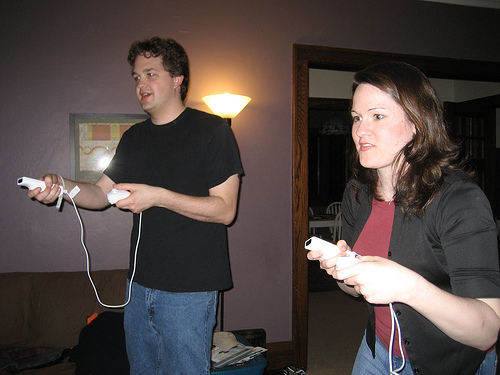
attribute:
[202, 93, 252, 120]
light — on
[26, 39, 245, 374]
man — playing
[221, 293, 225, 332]
pole — black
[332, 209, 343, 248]
chair — wooden, white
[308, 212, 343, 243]
table — white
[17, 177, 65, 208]
wiimote — white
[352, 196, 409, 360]
shirt — maroon, red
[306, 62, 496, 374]
woman — playing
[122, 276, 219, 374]
jeans — blue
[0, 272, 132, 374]
couch — brown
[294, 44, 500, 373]
door frame — wood, brown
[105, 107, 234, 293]
tshirt — black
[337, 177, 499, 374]
jacket — black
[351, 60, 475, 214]
hair — brown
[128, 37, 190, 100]
hair — brown